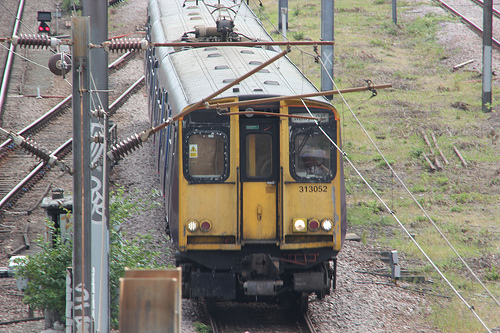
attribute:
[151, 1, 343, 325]
train — yellow, stopped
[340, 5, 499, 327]
field — grassy, brown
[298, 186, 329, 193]
number — black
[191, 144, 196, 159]
tag — yellow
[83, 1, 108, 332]
pole — gray, standing, metal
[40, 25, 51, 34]
lights — red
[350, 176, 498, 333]
grass — dark, green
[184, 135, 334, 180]
windows — framed, black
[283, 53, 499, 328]
wires — gray, for electricity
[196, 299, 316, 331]
tracks — straight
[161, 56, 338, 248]
caboose — yellow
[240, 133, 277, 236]
door — yellow